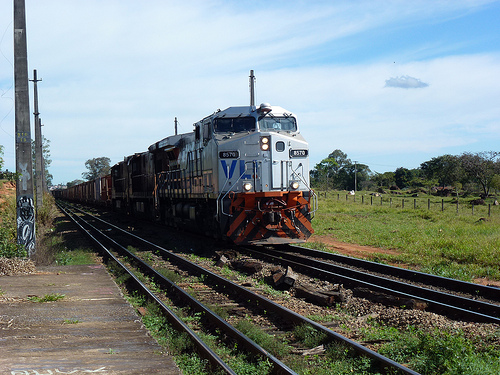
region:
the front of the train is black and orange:
[225, 191, 310, 224]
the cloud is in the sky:
[376, 76, 431, 93]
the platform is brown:
[15, 265, 100, 370]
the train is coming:
[155, 105, 332, 240]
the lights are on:
[257, 135, 272, 150]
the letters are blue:
[218, 159, 248, 180]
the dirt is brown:
[330, 245, 385, 255]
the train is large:
[95, 145, 301, 205]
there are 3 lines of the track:
[161, 270, 216, 325]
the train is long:
[49, 124, 336, 255]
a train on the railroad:
[50, 73, 440, 327]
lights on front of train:
[241, 130, 304, 196]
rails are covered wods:
[145, 244, 460, 353]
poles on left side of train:
[12, 3, 62, 263]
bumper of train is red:
[211, 187, 315, 244]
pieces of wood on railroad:
[211, 235, 374, 340]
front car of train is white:
[173, 97, 320, 209]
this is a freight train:
[58, 103, 317, 248]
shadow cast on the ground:
[44, 198, 151, 273]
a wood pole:
[3, 2, 42, 259]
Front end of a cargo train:
[195, 57, 327, 252]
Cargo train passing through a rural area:
[49, 63, 484, 268]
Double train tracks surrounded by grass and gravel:
[126, 260, 496, 360]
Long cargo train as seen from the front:
[56, 68, 315, 245]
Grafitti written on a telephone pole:
[8, 148, 40, 258]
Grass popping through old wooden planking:
[8, 268, 143, 371]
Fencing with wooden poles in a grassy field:
[328, 183, 488, 225]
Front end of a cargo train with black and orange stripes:
[190, 99, 317, 246]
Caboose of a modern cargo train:
[152, 104, 315, 243]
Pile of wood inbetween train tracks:
[225, 248, 354, 318]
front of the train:
[166, 78, 361, 248]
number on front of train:
[283, 141, 315, 166]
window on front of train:
[199, 102, 301, 149]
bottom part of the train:
[133, 191, 235, 244]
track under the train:
[289, 247, 356, 287]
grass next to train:
[355, 210, 404, 244]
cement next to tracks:
[45, 282, 118, 347]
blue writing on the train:
[210, 153, 256, 188]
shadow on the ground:
[84, 200, 151, 276]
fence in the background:
[353, 180, 458, 221]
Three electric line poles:
[8, 1, 63, 265]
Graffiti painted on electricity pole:
[10, 154, 41, 271]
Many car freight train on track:
[57, 69, 321, 246]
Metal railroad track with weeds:
[57, 197, 422, 374]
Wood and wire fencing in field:
[317, 188, 497, 238]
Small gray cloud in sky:
[377, 63, 442, 98]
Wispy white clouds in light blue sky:
[40, 27, 376, 106]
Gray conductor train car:
[148, 64, 313, 246]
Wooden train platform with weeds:
[0, 264, 178, 374]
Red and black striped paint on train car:
[205, 191, 315, 246]